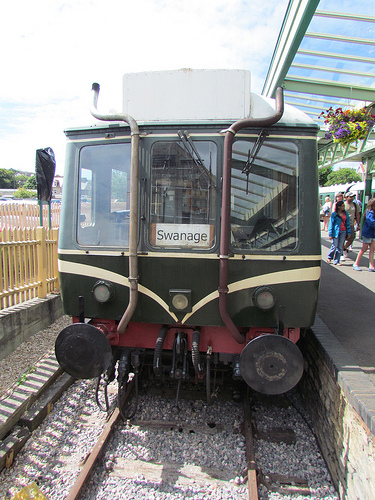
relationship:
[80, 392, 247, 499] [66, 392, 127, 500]
gravel on tracks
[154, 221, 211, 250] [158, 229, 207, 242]
sign says swanage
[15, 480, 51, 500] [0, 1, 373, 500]
zander took photo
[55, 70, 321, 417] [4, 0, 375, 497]
train at station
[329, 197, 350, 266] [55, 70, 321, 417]
passenger stepped out of train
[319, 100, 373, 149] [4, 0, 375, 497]
flowers on railway station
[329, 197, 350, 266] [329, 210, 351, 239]
woman in jacket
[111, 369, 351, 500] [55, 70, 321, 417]
shadow of train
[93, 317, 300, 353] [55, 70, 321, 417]
color at bottom of train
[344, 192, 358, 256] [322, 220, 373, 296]
person on platform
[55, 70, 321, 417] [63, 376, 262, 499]
train on tracks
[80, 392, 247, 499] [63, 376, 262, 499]
gravel between tracks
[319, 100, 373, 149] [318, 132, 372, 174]
flowers on structure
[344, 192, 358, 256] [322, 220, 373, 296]
person standing on platform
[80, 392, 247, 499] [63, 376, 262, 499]
gravel next to tracks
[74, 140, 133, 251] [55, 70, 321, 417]
window on a train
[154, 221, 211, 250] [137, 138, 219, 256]
sign in window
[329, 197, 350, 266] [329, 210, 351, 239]
passenger wearing jacket